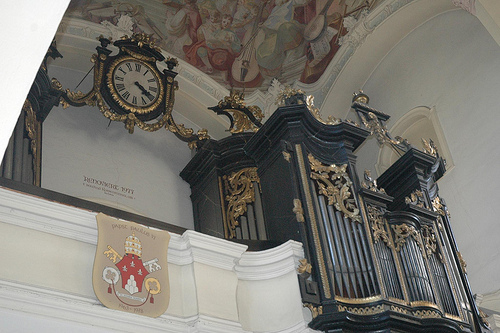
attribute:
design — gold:
[306, 151, 363, 228]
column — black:
[244, 109, 394, 331]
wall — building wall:
[339, 17, 496, 314]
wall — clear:
[341, 8, 497, 294]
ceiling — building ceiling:
[163, 21, 413, 131]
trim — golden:
[82, 29, 121, 82]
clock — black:
[98, 60, 197, 114]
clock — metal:
[88, 32, 173, 126]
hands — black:
[132, 80, 162, 100]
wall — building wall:
[4, 113, 204, 226]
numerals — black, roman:
[112, 59, 142, 109]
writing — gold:
[76, 171, 142, 203]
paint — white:
[334, 10, 484, 290]